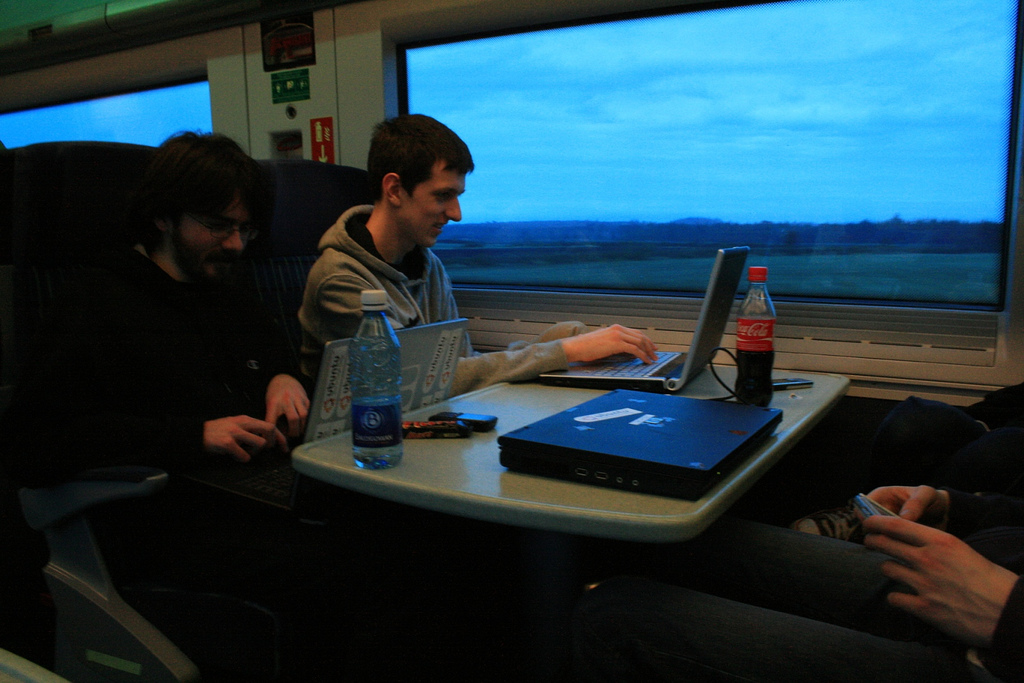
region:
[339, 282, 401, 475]
a plastic water bottle on a table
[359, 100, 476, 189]
a man with short hair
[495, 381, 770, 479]
a black laptop on a table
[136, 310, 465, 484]
a man using a laptop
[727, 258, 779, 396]
a drink bottle with a red lid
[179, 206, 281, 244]
a man wearing glasses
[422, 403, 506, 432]
a cell phone on a table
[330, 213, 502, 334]
a man wearing a grey sweatshirt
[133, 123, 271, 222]
a man with black hair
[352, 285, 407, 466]
a clear water bottle on a table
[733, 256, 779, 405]
a bottle with are lid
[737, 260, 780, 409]
a drink bottle on a table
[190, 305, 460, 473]
a silver laptop in a man's lap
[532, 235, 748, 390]
a silver laptop on a table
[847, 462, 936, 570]
a person holding a cell phone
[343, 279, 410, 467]
bottle of water on table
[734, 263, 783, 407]
bottle of coca cola on table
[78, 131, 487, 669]
man typing on laptop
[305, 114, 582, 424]
man is wearing gray sweatshirt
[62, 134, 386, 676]
man is wearing black sweatshirt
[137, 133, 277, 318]
man is wearing glasses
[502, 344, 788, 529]
cords going to laptop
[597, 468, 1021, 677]
man playing with cellphone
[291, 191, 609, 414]
Man wearing a sweatshirt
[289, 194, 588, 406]
Man is wearing a sweatshirt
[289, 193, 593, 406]
Man wearing a gray sweatshirt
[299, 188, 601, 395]
Man is wearing a gray sweatshirt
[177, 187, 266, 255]
Man wearing glasses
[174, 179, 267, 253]
Man is wearing glasses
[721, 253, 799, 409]
Plastic soda bottle on a table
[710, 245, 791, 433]
Plastic soda bottle is on a table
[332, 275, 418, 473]
Plastic water bottle on a table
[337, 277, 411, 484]
Plastic water bottle is on a table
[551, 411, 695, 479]
computer on the table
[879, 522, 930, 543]
finger on the hand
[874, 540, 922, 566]
finger on the hand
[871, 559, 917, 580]
finger on the hand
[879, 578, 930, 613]
finger on the hand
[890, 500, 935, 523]
finger on the hand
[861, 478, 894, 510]
finger on the hand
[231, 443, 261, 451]
finger on the hand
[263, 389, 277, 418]
finger on the hand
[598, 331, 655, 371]
finger on the hand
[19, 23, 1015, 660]
people traveling in a train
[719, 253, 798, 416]
a bottle of soda on a table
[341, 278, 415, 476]
a bottle of water on a table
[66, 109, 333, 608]
man wears black clothes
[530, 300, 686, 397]
hand on a keyboard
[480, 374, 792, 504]
a laptop on a table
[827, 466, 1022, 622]
hands holding a cell phone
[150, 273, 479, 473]
a laptop on a lap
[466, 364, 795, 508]
the laptop is close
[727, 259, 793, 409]
the bottles has a red label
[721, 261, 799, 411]
a bottle of coke on the table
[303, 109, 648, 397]
a person is sitting down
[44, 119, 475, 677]
a person is sitting down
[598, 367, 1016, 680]
a person is sitting down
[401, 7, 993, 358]
a window on a train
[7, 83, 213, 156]
a window on a train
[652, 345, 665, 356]
a key on a keyboard